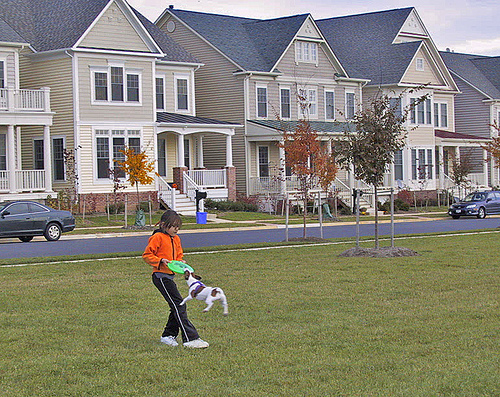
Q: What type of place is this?
A: It is a park.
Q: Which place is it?
A: It is a park.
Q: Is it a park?
A: Yes, it is a park.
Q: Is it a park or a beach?
A: It is a park.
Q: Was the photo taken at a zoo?
A: No, the picture was taken in a park.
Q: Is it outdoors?
A: Yes, it is outdoors.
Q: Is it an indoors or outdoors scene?
A: It is outdoors.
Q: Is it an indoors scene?
A: No, it is outdoors.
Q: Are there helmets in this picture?
A: No, there are no helmets.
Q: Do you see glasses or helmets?
A: No, there are no helmets or glasses.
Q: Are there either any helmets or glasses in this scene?
A: No, there are no helmets or glasses.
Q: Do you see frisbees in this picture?
A: Yes, there is a frisbee.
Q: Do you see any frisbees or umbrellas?
A: Yes, there is a frisbee.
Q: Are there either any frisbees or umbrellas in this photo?
A: Yes, there is a frisbee.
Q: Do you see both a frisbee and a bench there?
A: No, there is a frisbee but no benches.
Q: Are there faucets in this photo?
A: No, there are no faucets.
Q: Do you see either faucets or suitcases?
A: No, there are no faucets or suitcases.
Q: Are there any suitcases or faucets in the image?
A: No, there are no faucets or suitcases.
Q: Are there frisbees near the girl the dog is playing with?
A: Yes, there is a frisbee near the girl.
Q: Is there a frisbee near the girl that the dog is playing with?
A: Yes, there is a frisbee near the girl.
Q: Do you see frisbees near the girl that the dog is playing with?
A: Yes, there is a frisbee near the girl.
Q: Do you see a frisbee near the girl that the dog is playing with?
A: Yes, there is a frisbee near the girl.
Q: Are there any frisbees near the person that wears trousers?
A: Yes, there is a frisbee near the girl.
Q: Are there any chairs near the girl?
A: No, there is a frisbee near the girl.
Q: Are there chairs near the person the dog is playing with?
A: No, there is a frisbee near the girl.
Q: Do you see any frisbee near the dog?
A: Yes, there is a frisbee near the dog.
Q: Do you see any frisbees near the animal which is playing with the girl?
A: Yes, there is a frisbee near the dog.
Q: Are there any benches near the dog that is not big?
A: No, there is a frisbee near the dog.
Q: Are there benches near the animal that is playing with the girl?
A: No, there is a frisbee near the dog.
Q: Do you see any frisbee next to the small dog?
A: Yes, there is a frisbee next to the dog.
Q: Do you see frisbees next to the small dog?
A: Yes, there is a frisbee next to the dog.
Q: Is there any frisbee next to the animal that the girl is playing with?
A: Yes, there is a frisbee next to the dog.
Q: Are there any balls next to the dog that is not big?
A: No, there is a frisbee next to the dog.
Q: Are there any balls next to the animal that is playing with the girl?
A: No, there is a frisbee next to the dog.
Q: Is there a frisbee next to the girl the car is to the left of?
A: Yes, there is a frisbee next to the girl.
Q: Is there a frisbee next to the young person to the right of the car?
A: Yes, there is a frisbee next to the girl.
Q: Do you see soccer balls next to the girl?
A: No, there is a frisbee next to the girl.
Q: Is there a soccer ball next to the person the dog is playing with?
A: No, there is a frisbee next to the girl.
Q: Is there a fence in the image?
A: No, there are no fences.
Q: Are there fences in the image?
A: No, there are no fences.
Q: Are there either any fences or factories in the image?
A: No, there are no fences or factories.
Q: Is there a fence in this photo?
A: No, there are no fences.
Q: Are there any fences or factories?
A: No, there are no fences or factories.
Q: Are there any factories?
A: No, there are no factories.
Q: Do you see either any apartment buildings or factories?
A: No, there are no factories or apartment buildings.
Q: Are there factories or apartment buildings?
A: No, there are no factories or apartment buildings.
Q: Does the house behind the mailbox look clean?
A: Yes, the house is clean.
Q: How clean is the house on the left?
A: The house is clean.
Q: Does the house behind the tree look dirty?
A: No, the house is clean.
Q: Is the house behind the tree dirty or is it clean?
A: The house is clean.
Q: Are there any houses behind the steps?
A: Yes, there is a house behind the steps.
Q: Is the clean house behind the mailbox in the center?
A: Yes, the house is behind the mailbox.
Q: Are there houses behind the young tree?
A: Yes, there is a house behind the tree.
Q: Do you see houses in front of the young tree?
A: No, the house is behind the tree.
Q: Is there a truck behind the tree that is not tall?
A: No, there is a house behind the tree.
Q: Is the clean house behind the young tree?
A: Yes, the house is behind the tree.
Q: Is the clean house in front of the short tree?
A: No, the house is behind the tree.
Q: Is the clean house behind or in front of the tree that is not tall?
A: The house is behind the tree.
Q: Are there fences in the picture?
A: No, there are no fences.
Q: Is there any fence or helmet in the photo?
A: No, there are no fences or helmets.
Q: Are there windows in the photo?
A: Yes, there is a window.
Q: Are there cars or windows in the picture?
A: Yes, there is a window.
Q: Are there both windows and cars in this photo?
A: Yes, there are both a window and a car.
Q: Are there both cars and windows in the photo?
A: Yes, there are both a window and a car.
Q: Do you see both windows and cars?
A: Yes, there are both a window and a car.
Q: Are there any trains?
A: No, there are no trains.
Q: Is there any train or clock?
A: No, there are no trains or clocks.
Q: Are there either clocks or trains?
A: No, there are no trains or clocks.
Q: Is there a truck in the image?
A: No, there are no trucks.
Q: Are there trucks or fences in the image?
A: No, there are no trucks or fences.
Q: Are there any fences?
A: No, there are no fences.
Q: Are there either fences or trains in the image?
A: No, there are no fences or trains.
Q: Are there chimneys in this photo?
A: No, there are no chimneys.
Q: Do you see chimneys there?
A: No, there are no chimneys.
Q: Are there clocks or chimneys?
A: No, there are no chimneys or clocks.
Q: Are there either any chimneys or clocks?
A: No, there are no chimneys or clocks.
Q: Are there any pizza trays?
A: No, there are no pizza trays.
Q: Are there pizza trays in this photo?
A: No, there are no pizza trays.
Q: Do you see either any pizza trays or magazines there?
A: No, there are no pizza trays or magazines.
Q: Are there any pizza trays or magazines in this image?
A: No, there are no pizza trays or magazines.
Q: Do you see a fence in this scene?
A: No, there are no fences.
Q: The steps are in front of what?
A: The steps are in front of the house.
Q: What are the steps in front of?
A: The steps are in front of the house.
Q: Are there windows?
A: Yes, there is a window.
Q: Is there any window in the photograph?
A: Yes, there is a window.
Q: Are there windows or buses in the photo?
A: Yes, there is a window.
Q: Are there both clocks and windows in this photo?
A: No, there is a window but no clocks.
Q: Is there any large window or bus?
A: Yes, there is a large window.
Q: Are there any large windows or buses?
A: Yes, there is a large window.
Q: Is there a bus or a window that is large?
A: Yes, the window is large.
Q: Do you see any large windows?
A: Yes, there is a large window.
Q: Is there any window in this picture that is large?
A: Yes, there is a window that is large.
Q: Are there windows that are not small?
A: Yes, there is a large window.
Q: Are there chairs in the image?
A: No, there are no chairs.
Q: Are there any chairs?
A: No, there are no chairs.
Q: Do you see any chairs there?
A: No, there are no chairs.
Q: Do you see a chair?
A: No, there are no chairs.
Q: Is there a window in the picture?
A: Yes, there is a window.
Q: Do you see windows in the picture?
A: Yes, there is a window.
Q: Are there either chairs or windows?
A: Yes, there is a window.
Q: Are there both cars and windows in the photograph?
A: Yes, there are both a window and a car.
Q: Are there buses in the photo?
A: No, there are no buses.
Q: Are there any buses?
A: No, there are no buses.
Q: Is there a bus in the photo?
A: No, there are no buses.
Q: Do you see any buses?
A: No, there are no buses.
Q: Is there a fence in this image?
A: No, there are no fences.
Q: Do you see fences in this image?
A: No, there are no fences.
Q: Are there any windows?
A: Yes, there is a window.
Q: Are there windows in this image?
A: Yes, there is a window.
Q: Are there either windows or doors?
A: Yes, there is a window.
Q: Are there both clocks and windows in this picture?
A: No, there is a window but no clocks.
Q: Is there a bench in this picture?
A: No, there are no benches.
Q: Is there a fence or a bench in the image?
A: No, there are no benches or fences.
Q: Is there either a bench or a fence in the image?
A: No, there are no benches or fences.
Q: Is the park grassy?
A: Yes, the park is grassy.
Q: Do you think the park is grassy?
A: Yes, the park is grassy.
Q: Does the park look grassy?
A: Yes, the park is grassy.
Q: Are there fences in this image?
A: No, there are no fences.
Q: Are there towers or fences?
A: No, there are no fences or towers.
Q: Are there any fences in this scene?
A: No, there are no fences.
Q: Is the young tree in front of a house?
A: Yes, the tree is in front of a house.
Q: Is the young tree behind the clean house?
A: No, the tree is in front of the house.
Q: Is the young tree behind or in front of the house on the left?
A: The tree is in front of the house.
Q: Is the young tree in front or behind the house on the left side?
A: The tree is in front of the house.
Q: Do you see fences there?
A: No, there are no fences.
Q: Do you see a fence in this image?
A: No, there are no fences.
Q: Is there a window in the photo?
A: Yes, there is a window.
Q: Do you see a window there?
A: Yes, there is a window.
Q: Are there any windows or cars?
A: Yes, there is a window.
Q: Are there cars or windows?
A: Yes, there is a window.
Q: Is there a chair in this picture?
A: No, there are no chairs.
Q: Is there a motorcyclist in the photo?
A: No, there are no bikers.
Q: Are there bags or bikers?
A: No, there are no bikers or bags.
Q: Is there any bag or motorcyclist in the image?
A: No, there are no bikers or bags.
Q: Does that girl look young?
A: Yes, the girl is young.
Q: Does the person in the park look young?
A: Yes, the girl is young.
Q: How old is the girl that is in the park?
A: The girl is young.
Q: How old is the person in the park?
A: The girl is young.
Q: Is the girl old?
A: No, the girl is young.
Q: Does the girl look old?
A: No, the girl is young.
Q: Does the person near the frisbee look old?
A: No, the girl is young.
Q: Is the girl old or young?
A: The girl is young.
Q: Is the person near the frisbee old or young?
A: The girl is young.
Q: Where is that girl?
A: The girl is in the park.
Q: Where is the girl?
A: The girl is in the park.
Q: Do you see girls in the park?
A: Yes, there is a girl in the park.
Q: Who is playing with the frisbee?
A: The girl is playing with the frisbee.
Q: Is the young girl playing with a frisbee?
A: Yes, the girl is playing with a frisbee.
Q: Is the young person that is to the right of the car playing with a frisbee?
A: Yes, the girl is playing with a frisbee.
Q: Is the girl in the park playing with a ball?
A: No, the girl is playing with a frisbee.